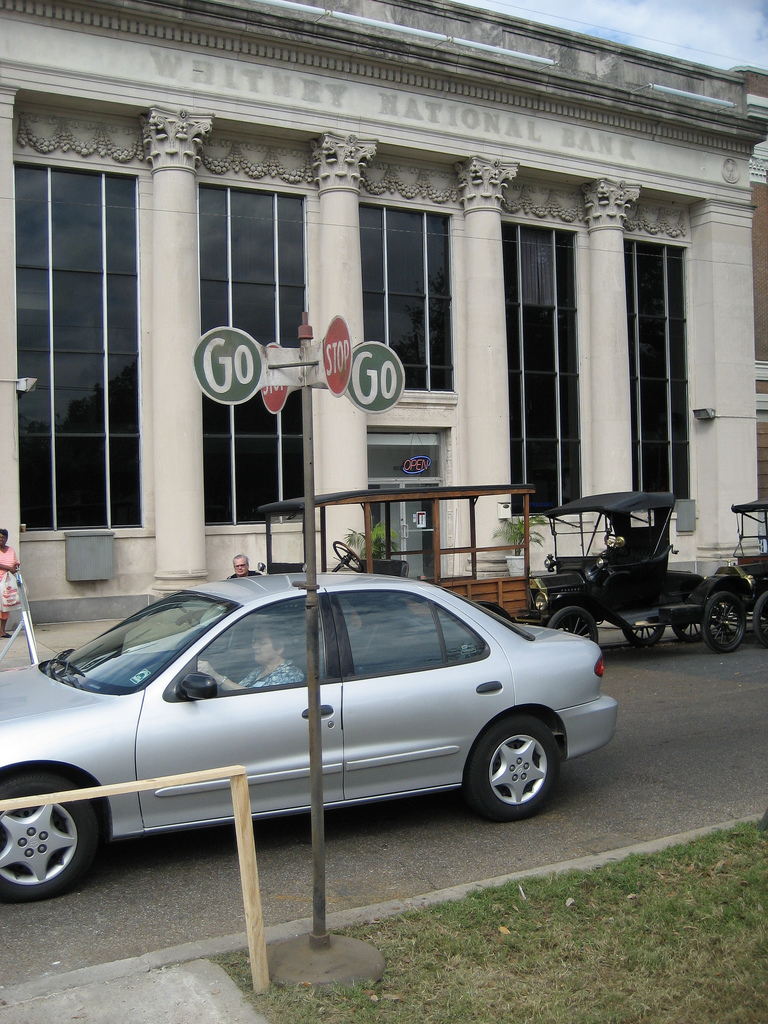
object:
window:
[432, 603, 484, 664]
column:
[454, 156, 511, 580]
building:
[0, 2, 766, 623]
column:
[581, 180, 641, 516]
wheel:
[0, 766, 99, 905]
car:
[0, 573, 618, 901]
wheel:
[463, 710, 561, 822]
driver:
[197, 611, 305, 691]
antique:
[515, 492, 708, 650]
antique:
[253, 484, 537, 619]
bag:
[0, 570, 22, 613]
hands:
[0, 566, 41, 668]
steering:
[332, 540, 365, 572]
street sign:
[323, 314, 354, 397]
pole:
[302, 386, 317, 584]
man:
[227, 555, 262, 582]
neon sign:
[402, 455, 432, 475]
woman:
[0, 529, 21, 639]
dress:
[0, 547, 20, 621]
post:
[292, 388, 331, 950]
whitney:
[149, 50, 635, 160]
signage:
[310, 132, 379, 197]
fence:
[0, 766, 271, 994]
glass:
[367, 433, 440, 488]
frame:
[500, 217, 526, 515]